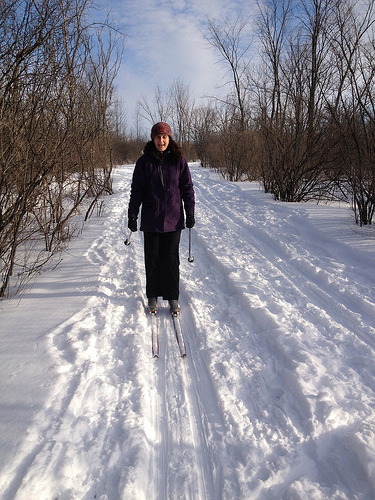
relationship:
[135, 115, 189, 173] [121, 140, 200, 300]
skier has outfit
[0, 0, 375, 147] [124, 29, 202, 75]
cloud in sky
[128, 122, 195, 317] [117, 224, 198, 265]
skier holds ski sticks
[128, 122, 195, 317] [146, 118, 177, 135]
skier wears hat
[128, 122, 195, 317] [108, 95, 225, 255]
skier wears coat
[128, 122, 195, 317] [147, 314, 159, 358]
skier has ski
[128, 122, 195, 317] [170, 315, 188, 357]
skier has ski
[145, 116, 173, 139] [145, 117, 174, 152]
hat on head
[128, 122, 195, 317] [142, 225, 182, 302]
skier wears pants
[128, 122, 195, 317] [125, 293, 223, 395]
skier on skis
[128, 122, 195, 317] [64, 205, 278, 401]
skier on snow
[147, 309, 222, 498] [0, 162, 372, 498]
ski tracks in snow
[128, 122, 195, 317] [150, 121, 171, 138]
skier wearing hat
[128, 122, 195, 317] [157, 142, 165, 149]
skier with open mouth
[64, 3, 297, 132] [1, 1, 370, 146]
cloud in sky